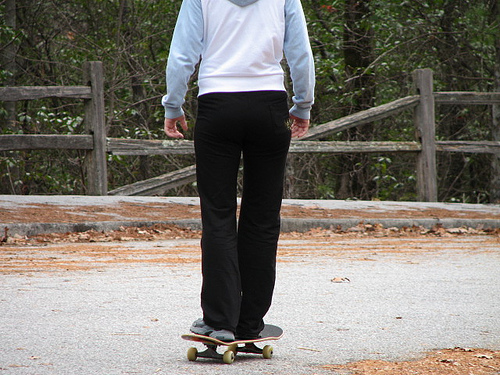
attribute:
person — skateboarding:
[162, 4, 319, 337]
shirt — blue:
[164, 4, 332, 103]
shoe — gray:
[183, 313, 233, 344]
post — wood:
[75, 54, 118, 195]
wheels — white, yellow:
[183, 344, 239, 370]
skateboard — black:
[174, 323, 284, 349]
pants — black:
[181, 88, 278, 336]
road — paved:
[4, 237, 500, 374]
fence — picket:
[9, 61, 496, 223]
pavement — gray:
[0, 192, 498, 239]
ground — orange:
[4, 206, 499, 272]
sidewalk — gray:
[2, 195, 499, 239]